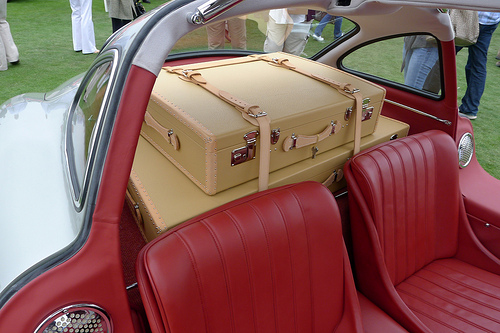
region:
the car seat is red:
[183, 212, 346, 327]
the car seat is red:
[354, 95, 485, 287]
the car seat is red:
[159, 159, 269, 304]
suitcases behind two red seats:
[122, 43, 427, 315]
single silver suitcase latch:
[245, 135, 259, 160]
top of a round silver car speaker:
[29, 303, 111, 331]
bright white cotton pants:
[65, 0, 97, 55]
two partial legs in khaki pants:
[205, 16, 249, 53]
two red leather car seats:
[136, 130, 498, 330]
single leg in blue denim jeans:
[402, 44, 439, 89]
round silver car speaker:
[459, 130, 476, 168]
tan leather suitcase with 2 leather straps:
[144, 49, 389, 194]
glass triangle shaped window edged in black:
[335, 28, 445, 108]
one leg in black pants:
[457, 21, 499, 120]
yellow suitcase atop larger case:
[135, 48, 398, 201]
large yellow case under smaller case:
[92, 100, 419, 242]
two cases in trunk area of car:
[88, 45, 419, 272]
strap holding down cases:
[248, 51, 378, 161]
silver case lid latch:
[227, 128, 258, 170]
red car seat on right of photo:
[342, 126, 499, 331]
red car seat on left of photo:
[128, 173, 400, 330]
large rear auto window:
[93, 0, 365, 85]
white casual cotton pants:
[62, 0, 106, 60]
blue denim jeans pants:
[399, 40, 442, 99]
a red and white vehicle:
[17, 4, 499, 331]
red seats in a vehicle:
[116, 133, 498, 332]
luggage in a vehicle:
[123, 52, 417, 219]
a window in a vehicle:
[331, 36, 452, 96]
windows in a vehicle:
[50, 0, 455, 150]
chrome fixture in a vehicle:
[28, 296, 119, 331]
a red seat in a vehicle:
[131, 175, 376, 331]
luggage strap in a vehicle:
[173, 61, 292, 176]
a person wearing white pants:
[58, 2, 115, 61]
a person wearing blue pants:
[466, 21, 492, 121]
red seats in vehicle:
[133, 130, 498, 332]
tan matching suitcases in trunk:
[112, 51, 410, 243]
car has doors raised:
[1, 1, 499, 331]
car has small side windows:
[61, 25, 447, 215]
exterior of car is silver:
[2, 0, 182, 304]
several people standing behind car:
[0, 2, 498, 119]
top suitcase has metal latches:
[228, 100, 379, 177]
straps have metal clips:
[126, 60, 363, 199]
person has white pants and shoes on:
[67, 2, 96, 52]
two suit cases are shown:
[96, 50, 408, 255]